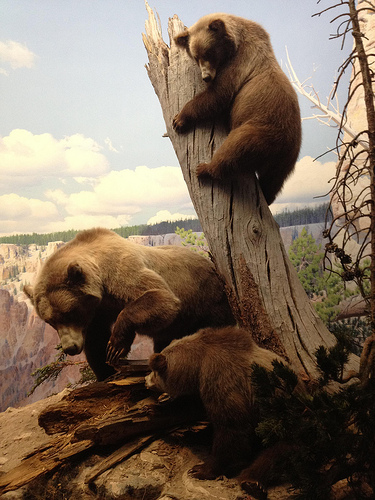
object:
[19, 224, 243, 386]
bear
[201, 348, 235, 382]
brown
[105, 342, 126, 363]
claws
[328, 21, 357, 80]
branch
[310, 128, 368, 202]
branch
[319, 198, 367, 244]
branch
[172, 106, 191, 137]
paw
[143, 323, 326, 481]
bears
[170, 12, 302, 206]
bear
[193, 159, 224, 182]
paw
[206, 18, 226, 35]
ear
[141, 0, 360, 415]
tree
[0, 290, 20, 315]
rocks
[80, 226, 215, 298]
back